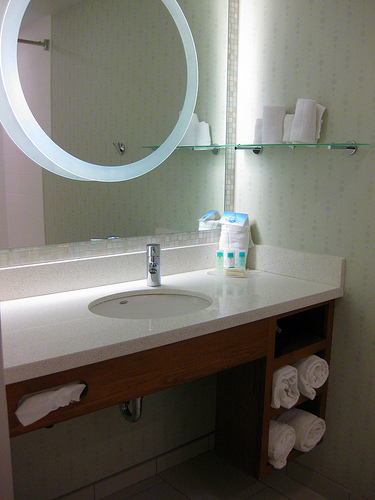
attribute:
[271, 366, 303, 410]
towel — rolled up, white, rolled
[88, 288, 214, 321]
sink — in hotel, circular, white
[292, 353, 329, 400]
towel — white, rolled, rolled up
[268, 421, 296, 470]
towel — white, rolled, rolled up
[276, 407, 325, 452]
towel — white, rolled, rolled up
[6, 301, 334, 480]
cabinet — brown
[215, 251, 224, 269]
shampoo — complimentary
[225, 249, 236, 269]
conditioner — complimentary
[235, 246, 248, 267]
lotion — complimentary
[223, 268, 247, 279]
soap — complimentary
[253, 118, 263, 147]
wash cloth — in restroom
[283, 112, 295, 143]
wash cloth — in restroom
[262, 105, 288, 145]
hand towel — in restroom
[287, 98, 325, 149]
hand towel — in restroom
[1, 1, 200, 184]
mirror — circular, lit, bordered in white, round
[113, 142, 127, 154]
hook — reflected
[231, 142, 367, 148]
shelf — glass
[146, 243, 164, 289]
faucet — knobless, gray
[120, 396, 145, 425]
pipe — silver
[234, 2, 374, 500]
wall — white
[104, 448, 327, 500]
floor — tiled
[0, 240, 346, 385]
counter — white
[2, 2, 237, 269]
mirror — larger